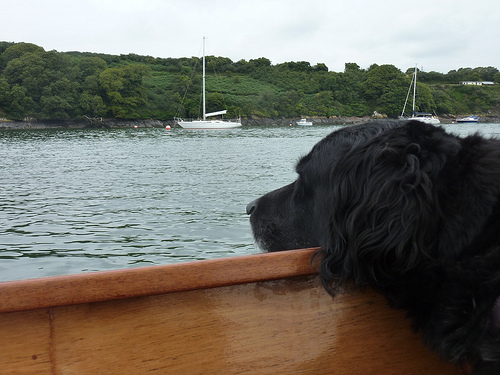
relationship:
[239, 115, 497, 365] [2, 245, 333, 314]
dog on ledge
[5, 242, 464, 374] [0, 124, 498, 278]
boat on water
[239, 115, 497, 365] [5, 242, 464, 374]
dog on boat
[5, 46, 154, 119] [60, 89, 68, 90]
trees with leaves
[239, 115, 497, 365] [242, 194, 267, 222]
dog has nose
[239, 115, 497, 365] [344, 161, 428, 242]
dog has fur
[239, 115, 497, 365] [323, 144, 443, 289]
dog has ears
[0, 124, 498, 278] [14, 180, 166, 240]
water shows ripples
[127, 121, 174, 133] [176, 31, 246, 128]
buoys next to boat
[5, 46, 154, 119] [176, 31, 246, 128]
trees behind boat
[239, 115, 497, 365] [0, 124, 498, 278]
dog on water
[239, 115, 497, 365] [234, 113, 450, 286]
dog with head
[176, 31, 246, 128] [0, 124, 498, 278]
boat in water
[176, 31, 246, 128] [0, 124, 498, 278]
boat on water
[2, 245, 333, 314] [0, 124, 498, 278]
ledge of water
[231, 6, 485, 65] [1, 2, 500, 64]
clouds against sky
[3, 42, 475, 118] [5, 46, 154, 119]
forest of trees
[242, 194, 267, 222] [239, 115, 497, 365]
nose on dog